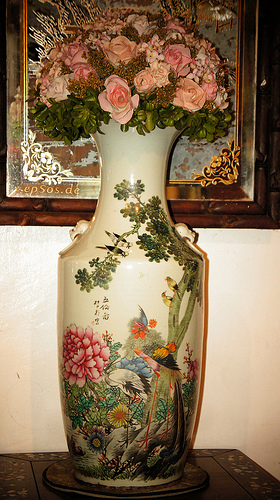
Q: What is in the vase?
A: Flowers.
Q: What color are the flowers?
A: Pink.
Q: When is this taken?
A: During the day.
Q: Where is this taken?
A: In a building.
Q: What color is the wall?
A: White.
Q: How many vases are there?
A: One.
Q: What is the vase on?
A: A table.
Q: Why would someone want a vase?
A: For decoration.